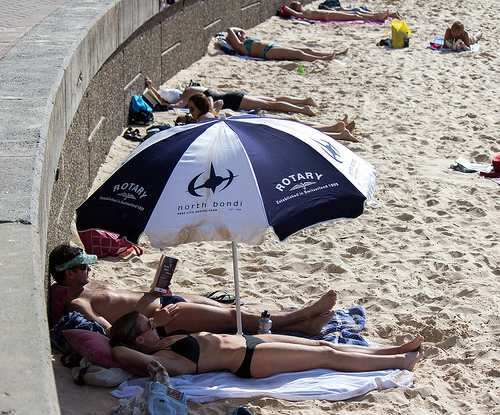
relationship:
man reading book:
[50, 246, 335, 337] [153, 252, 179, 293]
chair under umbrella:
[78, 225, 134, 257] [77, 116, 371, 245]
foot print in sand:
[420, 212, 454, 236] [67, 1, 499, 414]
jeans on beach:
[50, 310, 101, 340] [67, 1, 499, 414]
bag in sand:
[388, 17, 407, 49] [67, 1, 499, 414]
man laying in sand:
[50, 246, 335, 337] [67, 1, 499, 414]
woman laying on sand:
[107, 310, 424, 376] [67, 1, 499, 414]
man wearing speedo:
[50, 246, 335, 337] [156, 292, 182, 334]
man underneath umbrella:
[50, 246, 335, 337] [77, 116, 371, 245]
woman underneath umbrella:
[107, 310, 424, 376] [77, 116, 371, 245]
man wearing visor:
[50, 246, 335, 337] [58, 252, 99, 270]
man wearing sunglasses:
[50, 246, 335, 337] [71, 260, 89, 270]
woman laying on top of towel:
[107, 310, 424, 376] [134, 353, 410, 402]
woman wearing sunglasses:
[107, 310, 424, 376] [145, 320, 154, 329]